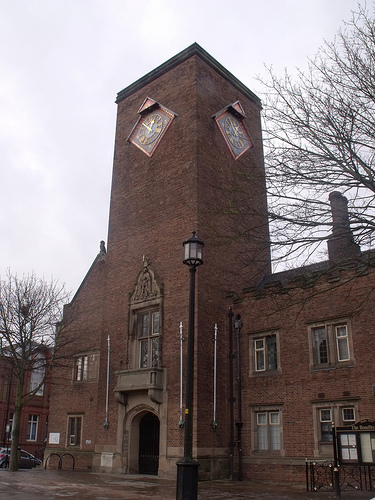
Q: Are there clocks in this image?
A: Yes, there is a clock.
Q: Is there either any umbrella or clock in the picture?
A: Yes, there is a clock.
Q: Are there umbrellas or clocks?
A: Yes, there is a clock.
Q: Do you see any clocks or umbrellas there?
A: Yes, there is a clock.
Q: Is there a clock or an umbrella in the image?
A: Yes, there is a clock.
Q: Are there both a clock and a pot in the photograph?
A: No, there is a clock but no pots.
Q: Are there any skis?
A: No, there are no skis.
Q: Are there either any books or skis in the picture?
A: No, there are no skis or books.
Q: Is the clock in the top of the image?
A: Yes, the clock is in the top of the image.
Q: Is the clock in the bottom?
A: No, the clock is in the top of the image.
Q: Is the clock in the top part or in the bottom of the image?
A: The clock is in the top of the image.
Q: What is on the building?
A: The clock is on the building.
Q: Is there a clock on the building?
A: Yes, there is a clock on the building.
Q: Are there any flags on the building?
A: No, there is a clock on the building.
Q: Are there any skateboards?
A: No, there are no skateboards.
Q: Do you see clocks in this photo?
A: Yes, there is a clock.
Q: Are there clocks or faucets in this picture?
A: Yes, there is a clock.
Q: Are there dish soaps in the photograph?
A: No, there are no dish soaps.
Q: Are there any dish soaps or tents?
A: No, there are no dish soaps or tents.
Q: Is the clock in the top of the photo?
A: Yes, the clock is in the top of the image.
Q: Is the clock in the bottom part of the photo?
A: No, the clock is in the top of the image.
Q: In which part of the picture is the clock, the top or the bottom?
A: The clock is in the top of the image.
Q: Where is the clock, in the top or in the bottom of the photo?
A: The clock is in the top of the image.